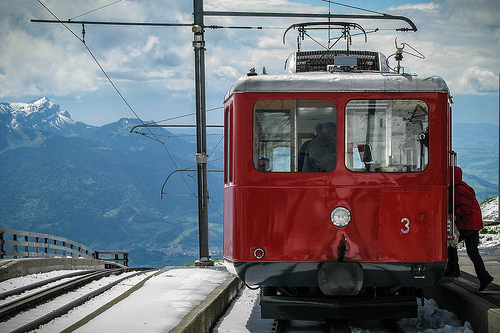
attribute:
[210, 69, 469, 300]
train — red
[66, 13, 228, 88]
clouds — white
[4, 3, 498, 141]
sky — blue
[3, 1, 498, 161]
sky — blue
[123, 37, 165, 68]
clouds — white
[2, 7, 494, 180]
sky — blue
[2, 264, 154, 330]
tracks — railroad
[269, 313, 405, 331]
tracks — railroad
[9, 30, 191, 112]
clouds — white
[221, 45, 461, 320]
train — red , trolley, for passenger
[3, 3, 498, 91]
clouds — white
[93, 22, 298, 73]
sky — blue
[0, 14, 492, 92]
clouds — white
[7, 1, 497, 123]
clouds — white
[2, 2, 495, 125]
sky — blue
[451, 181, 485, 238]
shirt — red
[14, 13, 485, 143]
sky — blue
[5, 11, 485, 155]
sky — blue